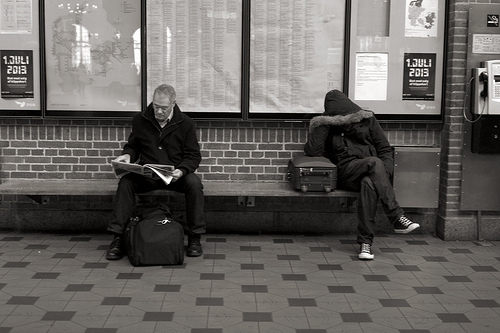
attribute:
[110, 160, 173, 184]
newspaper — black, white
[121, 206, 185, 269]
bag — black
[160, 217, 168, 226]
zipper — silver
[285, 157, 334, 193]
suitcase — black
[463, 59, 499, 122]
phone — payphone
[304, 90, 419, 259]
person — sleeping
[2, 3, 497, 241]
wall — brick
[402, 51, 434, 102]
poster — black, white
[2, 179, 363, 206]
bench — long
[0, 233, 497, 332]
floor — black, gray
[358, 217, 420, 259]
shoes — black, white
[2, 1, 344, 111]
window — reflecting